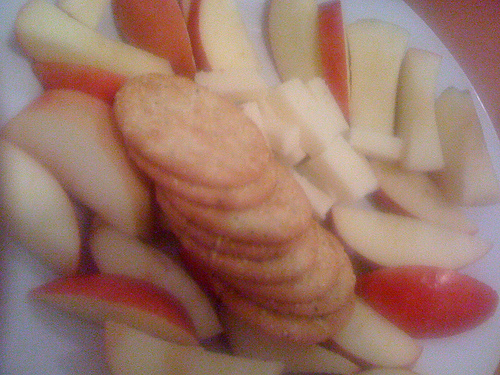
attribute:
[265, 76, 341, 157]
cheese — rectangular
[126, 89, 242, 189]
cracker — crispy, brown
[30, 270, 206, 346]
apple slice — red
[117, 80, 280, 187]
cracker — crispy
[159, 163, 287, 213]
cracker — crispy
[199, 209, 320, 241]
cracker — crispy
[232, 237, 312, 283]
cracker — crispy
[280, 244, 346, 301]
cracker — crispy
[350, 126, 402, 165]
cheese — rectangular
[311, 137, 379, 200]
cheese — rectangular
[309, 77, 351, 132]
cheese — rectangular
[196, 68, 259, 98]
cheese — rectangular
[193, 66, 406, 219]
cheese — small